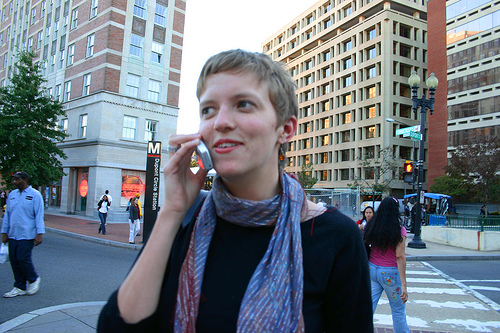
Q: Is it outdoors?
A: Yes, it is outdoors.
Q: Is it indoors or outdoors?
A: It is outdoors.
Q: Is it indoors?
A: No, it is outdoors.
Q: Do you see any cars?
A: No, there are no cars.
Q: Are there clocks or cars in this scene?
A: No, there are no cars or clocks.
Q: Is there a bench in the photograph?
A: No, there are no benches.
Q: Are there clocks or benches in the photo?
A: No, there are no benches or clocks.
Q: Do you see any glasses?
A: No, there are no glasses.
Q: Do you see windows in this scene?
A: Yes, there are windows.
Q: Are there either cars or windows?
A: Yes, there are windows.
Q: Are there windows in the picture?
A: Yes, there are windows.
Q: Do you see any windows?
A: Yes, there are windows.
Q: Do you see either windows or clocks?
A: Yes, there are windows.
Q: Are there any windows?
A: Yes, there are windows.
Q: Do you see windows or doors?
A: Yes, there are windows.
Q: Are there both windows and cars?
A: No, there are windows but no cars.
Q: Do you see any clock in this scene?
A: No, there are no clocks.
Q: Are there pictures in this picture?
A: No, there are no pictures.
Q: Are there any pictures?
A: No, there are no pictures.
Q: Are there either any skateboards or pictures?
A: No, there are no pictures or skateboards.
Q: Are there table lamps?
A: No, there are no table lamps.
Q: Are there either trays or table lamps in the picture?
A: No, there are no table lamps or trays.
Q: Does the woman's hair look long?
A: Yes, the hair is long.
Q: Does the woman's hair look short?
A: No, the hair is long.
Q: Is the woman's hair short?
A: No, the hair is long.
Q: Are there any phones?
A: Yes, there is a phone.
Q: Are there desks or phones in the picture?
A: Yes, there is a phone.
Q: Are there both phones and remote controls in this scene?
A: No, there is a phone but no remote controls.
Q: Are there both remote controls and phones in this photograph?
A: No, there is a phone but no remote controls.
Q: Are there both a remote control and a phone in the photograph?
A: No, there is a phone but no remote controls.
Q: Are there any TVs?
A: No, there are no tvs.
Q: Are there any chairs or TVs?
A: No, there are no TVs or chairs.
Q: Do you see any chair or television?
A: No, there are no televisions or chairs.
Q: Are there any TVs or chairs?
A: No, there are no TVs or chairs.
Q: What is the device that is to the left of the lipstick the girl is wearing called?
A: The device is a phone.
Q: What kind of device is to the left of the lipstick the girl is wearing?
A: The device is a phone.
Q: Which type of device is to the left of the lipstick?
A: The device is a phone.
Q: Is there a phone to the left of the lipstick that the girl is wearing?
A: Yes, there is a phone to the left of the lipstick.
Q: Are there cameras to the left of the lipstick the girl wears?
A: No, there is a phone to the left of the lipstick.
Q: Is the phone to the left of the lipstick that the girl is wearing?
A: Yes, the phone is to the left of the lipstick.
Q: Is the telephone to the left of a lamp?
A: No, the telephone is to the left of the lipstick.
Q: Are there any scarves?
A: Yes, there is a scarf.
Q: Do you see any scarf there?
A: Yes, there is a scarf.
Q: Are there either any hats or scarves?
A: Yes, there is a scarf.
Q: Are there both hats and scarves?
A: No, there is a scarf but no hats.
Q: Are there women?
A: Yes, there is a woman.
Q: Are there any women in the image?
A: Yes, there is a woman.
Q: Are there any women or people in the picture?
A: Yes, there is a woman.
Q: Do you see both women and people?
A: Yes, there are both a woman and a person.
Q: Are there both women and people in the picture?
A: Yes, there are both a woman and a person.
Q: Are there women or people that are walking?
A: Yes, the woman is walking.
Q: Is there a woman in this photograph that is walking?
A: Yes, there is a woman that is walking.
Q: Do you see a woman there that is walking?
A: Yes, there is a woman that is walking.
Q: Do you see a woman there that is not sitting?
A: Yes, there is a woman that is walking .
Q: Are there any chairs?
A: No, there are no chairs.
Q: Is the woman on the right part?
A: Yes, the woman is on the right of the image.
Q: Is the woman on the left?
A: No, the woman is on the right of the image.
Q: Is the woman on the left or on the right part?
A: The woman is on the right of the image.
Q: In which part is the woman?
A: The woman is on the right of the image.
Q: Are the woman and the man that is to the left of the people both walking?
A: Yes, both the woman and the man are walking.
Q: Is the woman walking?
A: Yes, the woman is walking.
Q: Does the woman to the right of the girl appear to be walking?
A: Yes, the woman is walking.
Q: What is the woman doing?
A: The woman is walking.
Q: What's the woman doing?
A: The woman is walking.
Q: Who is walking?
A: The woman is walking.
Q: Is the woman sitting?
A: No, the woman is walking.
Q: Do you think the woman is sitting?
A: No, the woman is walking.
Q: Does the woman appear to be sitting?
A: No, the woman is walking.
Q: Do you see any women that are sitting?
A: No, there is a woman but she is walking.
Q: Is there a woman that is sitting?
A: No, there is a woman but she is walking.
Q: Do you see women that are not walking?
A: No, there is a woman but she is walking.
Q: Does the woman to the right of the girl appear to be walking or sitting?
A: The woman is walking.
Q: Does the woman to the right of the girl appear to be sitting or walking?
A: The woman is walking.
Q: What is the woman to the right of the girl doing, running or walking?
A: The woman is walking.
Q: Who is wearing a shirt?
A: The woman is wearing a shirt.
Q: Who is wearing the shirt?
A: The woman is wearing a shirt.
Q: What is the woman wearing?
A: The woman is wearing a shirt.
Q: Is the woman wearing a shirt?
A: Yes, the woman is wearing a shirt.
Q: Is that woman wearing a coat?
A: No, the woman is wearing a shirt.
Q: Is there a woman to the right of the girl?
A: Yes, there is a woman to the right of the girl.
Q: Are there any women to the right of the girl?
A: Yes, there is a woman to the right of the girl.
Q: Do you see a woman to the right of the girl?
A: Yes, there is a woman to the right of the girl.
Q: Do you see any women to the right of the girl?
A: Yes, there is a woman to the right of the girl.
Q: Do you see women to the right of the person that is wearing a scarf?
A: Yes, there is a woman to the right of the girl.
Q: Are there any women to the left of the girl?
A: No, the woman is to the right of the girl.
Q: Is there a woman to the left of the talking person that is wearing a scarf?
A: No, the woman is to the right of the girl.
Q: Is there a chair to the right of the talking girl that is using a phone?
A: No, there is a woman to the right of the girl.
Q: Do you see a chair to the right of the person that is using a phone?
A: No, there is a woman to the right of the girl.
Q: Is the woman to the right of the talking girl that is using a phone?
A: Yes, the woman is to the right of the girl.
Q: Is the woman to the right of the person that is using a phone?
A: Yes, the woman is to the right of the girl.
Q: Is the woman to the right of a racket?
A: No, the woman is to the right of the girl.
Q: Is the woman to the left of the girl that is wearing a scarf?
A: No, the woman is to the right of the girl.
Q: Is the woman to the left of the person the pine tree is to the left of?
A: No, the woman is to the right of the girl.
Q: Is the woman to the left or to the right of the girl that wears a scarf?
A: The woman is to the right of the girl.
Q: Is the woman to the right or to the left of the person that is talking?
A: The woman is to the right of the girl.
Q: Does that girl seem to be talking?
A: Yes, the girl is talking.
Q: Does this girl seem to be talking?
A: Yes, the girl is talking.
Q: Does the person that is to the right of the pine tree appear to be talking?
A: Yes, the girl is talking.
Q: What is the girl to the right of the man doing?
A: The girl is talking.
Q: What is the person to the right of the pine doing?
A: The girl is talking.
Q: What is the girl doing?
A: The girl is talking.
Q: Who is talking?
A: The girl is talking.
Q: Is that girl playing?
A: No, the girl is talking.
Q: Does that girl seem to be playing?
A: No, the girl is talking.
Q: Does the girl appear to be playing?
A: No, the girl is talking.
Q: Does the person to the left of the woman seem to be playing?
A: No, the girl is talking.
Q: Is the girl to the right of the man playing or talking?
A: The girl is talking.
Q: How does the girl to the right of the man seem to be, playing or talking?
A: The girl is talking.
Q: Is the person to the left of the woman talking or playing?
A: The girl is talking.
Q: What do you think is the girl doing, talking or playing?
A: The girl is talking.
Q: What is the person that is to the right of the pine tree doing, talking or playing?
A: The girl is talking.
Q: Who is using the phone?
A: The girl is using the phone.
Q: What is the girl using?
A: The girl is using a phone.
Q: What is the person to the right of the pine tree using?
A: The girl is using a phone.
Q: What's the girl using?
A: The girl is using a phone.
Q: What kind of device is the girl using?
A: The girl is using a phone.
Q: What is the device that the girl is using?
A: The device is a phone.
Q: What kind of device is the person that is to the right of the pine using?
A: The girl is using a phone.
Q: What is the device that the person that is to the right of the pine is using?
A: The device is a phone.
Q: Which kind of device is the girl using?
A: The girl is using a phone.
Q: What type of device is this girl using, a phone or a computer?
A: The girl is using a phone.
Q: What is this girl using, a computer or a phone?
A: The girl is using a phone.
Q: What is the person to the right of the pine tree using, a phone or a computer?
A: The girl is using a phone.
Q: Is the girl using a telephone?
A: Yes, the girl is using a telephone.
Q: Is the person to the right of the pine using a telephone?
A: Yes, the girl is using a telephone.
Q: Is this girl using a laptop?
A: No, the girl is using a telephone.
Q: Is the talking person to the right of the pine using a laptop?
A: No, the girl is using a telephone.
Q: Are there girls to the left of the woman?
A: Yes, there is a girl to the left of the woman.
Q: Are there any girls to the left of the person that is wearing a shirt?
A: Yes, there is a girl to the left of the woman.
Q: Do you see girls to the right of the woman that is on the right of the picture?
A: No, the girl is to the left of the woman.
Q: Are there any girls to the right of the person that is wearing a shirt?
A: No, the girl is to the left of the woman.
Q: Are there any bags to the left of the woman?
A: No, there is a girl to the left of the woman.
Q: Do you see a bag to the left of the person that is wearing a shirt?
A: No, there is a girl to the left of the woman.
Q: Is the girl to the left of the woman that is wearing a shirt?
A: Yes, the girl is to the left of the woman.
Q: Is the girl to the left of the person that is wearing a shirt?
A: Yes, the girl is to the left of the woman.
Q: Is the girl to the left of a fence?
A: No, the girl is to the left of the woman.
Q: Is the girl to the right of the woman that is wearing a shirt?
A: No, the girl is to the left of the woman.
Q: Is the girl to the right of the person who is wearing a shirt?
A: No, the girl is to the left of the woman.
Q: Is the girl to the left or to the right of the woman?
A: The girl is to the left of the woman.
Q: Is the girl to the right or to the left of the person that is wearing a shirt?
A: The girl is to the left of the woman.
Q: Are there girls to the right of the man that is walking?
A: Yes, there is a girl to the right of the man.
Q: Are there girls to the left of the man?
A: No, the girl is to the right of the man.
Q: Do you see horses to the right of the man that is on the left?
A: No, there is a girl to the right of the man.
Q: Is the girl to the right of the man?
A: Yes, the girl is to the right of the man.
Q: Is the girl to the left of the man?
A: No, the girl is to the right of the man.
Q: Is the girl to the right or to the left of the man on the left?
A: The girl is to the right of the man.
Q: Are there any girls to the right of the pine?
A: Yes, there is a girl to the right of the pine.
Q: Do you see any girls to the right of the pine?
A: Yes, there is a girl to the right of the pine.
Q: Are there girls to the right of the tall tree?
A: Yes, there is a girl to the right of the pine.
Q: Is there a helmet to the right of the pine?
A: No, there is a girl to the right of the pine.